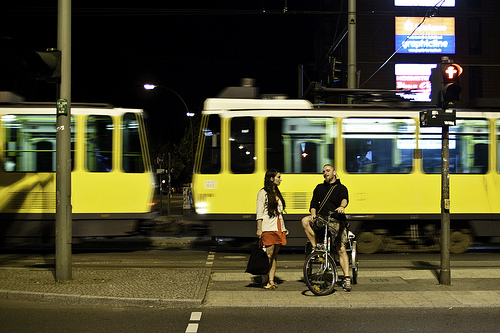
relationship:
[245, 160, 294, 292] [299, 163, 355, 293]
girl talking to man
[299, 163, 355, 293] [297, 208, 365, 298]
man holding bicycle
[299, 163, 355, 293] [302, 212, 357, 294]
man sitting on bicycle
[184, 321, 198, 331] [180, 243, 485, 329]
line marking crosswalk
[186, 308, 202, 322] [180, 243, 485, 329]
line marking crosswalk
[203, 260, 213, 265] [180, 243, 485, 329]
line marking crosswalk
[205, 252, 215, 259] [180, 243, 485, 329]
line marking crosswalk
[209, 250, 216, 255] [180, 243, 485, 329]
line marking crosswalk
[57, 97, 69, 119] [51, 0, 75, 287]
sign mounted on pole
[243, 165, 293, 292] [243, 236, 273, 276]
girl carrying backpack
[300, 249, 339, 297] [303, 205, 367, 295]
tire mounted on bicycle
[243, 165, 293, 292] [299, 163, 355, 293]
girl talking to man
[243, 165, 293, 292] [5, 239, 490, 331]
girl standing in street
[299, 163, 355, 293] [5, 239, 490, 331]
man standing in street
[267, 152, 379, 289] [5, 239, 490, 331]
bicycle standing on street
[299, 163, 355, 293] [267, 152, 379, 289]
man sitting on bicycle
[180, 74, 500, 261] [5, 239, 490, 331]
bus riding in street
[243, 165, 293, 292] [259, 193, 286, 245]
girl wearing dress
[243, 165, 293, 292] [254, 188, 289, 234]
girl wearing jacket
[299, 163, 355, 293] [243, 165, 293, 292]
man talking to girl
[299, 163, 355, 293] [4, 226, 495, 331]
man standing in street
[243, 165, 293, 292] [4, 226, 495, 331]
girl standing in street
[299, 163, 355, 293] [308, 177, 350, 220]
man wearing black jacket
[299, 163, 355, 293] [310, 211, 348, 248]
man wearing shorts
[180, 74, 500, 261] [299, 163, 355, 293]
bus by man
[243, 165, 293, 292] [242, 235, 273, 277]
girl carrying bag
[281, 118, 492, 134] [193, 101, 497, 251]
lights in train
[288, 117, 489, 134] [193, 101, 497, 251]
lights in train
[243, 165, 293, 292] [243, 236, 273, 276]
girl holding backpack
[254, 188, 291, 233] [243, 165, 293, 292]
jacket on girl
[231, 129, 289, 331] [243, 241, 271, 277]
woman holding handbag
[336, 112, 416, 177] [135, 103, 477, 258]
window on car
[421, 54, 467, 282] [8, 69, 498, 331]
light on corner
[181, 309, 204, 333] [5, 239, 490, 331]
line on street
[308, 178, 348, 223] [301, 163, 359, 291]
black jacket on man